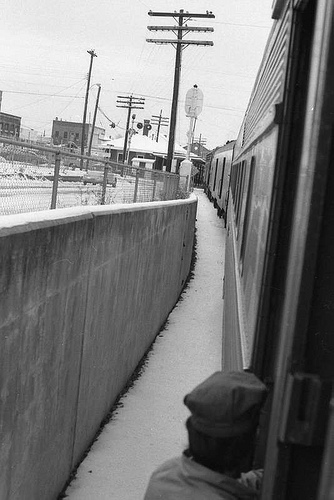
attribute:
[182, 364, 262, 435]
engineer's cap — dark train 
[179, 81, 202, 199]
pole — train equipment signal 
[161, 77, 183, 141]
pole —  telephone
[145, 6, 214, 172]
electric pole — wooden, tall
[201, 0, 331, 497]
train — motion 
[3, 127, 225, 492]
train station — city 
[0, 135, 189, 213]
fence — chain link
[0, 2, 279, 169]
sky — light , daytime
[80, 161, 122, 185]
car — single 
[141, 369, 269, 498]
worker — train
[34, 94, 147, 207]
buildings — plain , detailed boxy 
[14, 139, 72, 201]
fence — metal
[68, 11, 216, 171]
poles — line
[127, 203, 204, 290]
wall — cement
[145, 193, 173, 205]
snow — white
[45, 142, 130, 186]
car — motion, older style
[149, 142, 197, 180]
shelter — waiting 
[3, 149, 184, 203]
metal fencing — metal 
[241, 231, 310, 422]
doorway — train 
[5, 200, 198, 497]
wall — solid 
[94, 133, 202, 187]
building — train 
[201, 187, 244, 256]
tracks —  down 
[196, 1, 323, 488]
train — beside , alongside , side 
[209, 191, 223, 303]
tracks — train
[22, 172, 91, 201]
street — snowy 